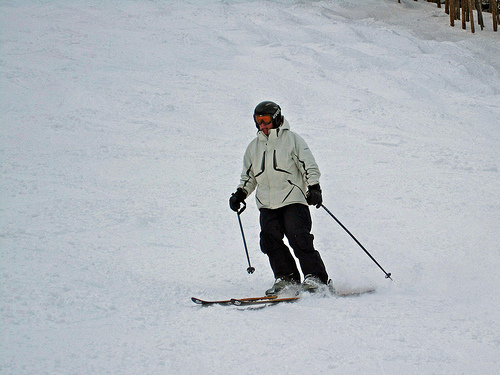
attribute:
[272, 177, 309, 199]
line — black 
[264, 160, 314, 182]
pants — black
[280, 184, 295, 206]
line — black 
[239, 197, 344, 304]
pants —  Black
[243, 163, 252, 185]
line — black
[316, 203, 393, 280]
ski pole — black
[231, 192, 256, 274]
ski pole — black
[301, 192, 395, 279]
pole — black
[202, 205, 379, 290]
pants — black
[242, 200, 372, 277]
pants — black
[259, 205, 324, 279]
pants — Black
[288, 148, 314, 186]
line — black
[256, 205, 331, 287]
pants —  black 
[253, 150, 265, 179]
line — black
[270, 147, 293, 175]
line — black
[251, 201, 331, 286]
pants — black